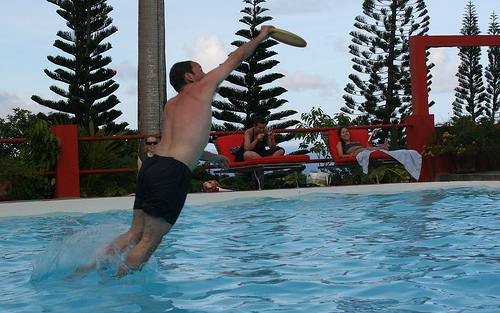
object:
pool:
[0, 184, 499, 313]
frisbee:
[268, 27, 308, 48]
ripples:
[250, 230, 304, 246]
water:
[0, 216, 499, 312]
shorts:
[133, 153, 193, 225]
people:
[337, 126, 409, 157]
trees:
[30, 0, 128, 170]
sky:
[167, 2, 466, 84]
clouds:
[193, 36, 246, 65]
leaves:
[92, 72, 106, 80]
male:
[61, 25, 276, 287]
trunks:
[137, 0, 167, 157]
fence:
[1, 125, 162, 205]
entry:
[434, 170, 500, 181]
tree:
[209, 0, 313, 165]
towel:
[356, 149, 422, 181]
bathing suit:
[343, 142, 364, 154]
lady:
[236, 118, 285, 162]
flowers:
[443, 131, 450, 137]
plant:
[453, 115, 481, 174]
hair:
[169, 61, 195, 92]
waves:
[12, 219, 104, 285]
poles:
[48, 124, 81, 198]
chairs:
[213, 134, 311, 193]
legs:
[96, 203, 184, 285]